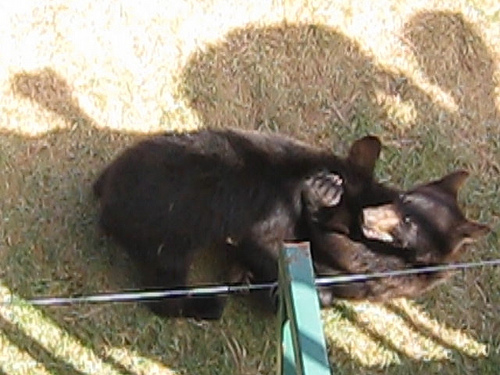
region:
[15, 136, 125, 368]
the grass is dry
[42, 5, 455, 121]
sunlight on the grass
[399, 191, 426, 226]
bear eyes are black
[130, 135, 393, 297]
the fur is black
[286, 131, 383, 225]
the paws are black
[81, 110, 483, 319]
black bear raising paws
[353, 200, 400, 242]
cream colored snout on bear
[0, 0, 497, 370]
grass and hay covering earth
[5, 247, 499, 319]
wire across fence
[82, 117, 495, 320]
bear on back with head and arms in air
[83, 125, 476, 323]
black bear rolling in hay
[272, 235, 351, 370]
green metal gate enclosure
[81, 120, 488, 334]
black bear in zoo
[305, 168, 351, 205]
large claws on black bear paw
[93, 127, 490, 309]
Bear rolling on the ground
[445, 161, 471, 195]
Ear on bear's head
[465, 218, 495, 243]
Ear on bear's head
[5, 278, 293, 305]
Wire pole on fence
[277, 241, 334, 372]
Green metal frame on a fence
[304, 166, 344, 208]
Large brown bear paw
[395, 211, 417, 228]
Eye in bear's face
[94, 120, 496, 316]
Two bears wrestling on the ground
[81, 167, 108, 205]
Stubby brown tail on a bear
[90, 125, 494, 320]
Two black bear cubs playing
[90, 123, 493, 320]
Two bear cubs wrestling on the ground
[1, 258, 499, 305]
Thick gray cable running through metal brace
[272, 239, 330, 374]
Green metal structure under observation deck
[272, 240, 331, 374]
Brace made of green rectangular tubing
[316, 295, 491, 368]
Shadow of rails on observation deck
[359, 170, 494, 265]
Head of black bear cub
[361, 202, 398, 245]
Brown muzzle of black bear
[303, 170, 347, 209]
Bear's front paw gripping other bear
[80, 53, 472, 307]
the bears are black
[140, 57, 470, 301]
these are bear cubs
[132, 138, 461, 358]
the bears are small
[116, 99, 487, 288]
there are two bears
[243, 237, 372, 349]
the fence post is green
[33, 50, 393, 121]
the grass is brown and dry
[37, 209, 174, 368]
there are patches of green grass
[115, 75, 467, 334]
two brown bears playing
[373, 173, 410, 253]
light brown muzzle of bear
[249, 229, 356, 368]
green metal fence support